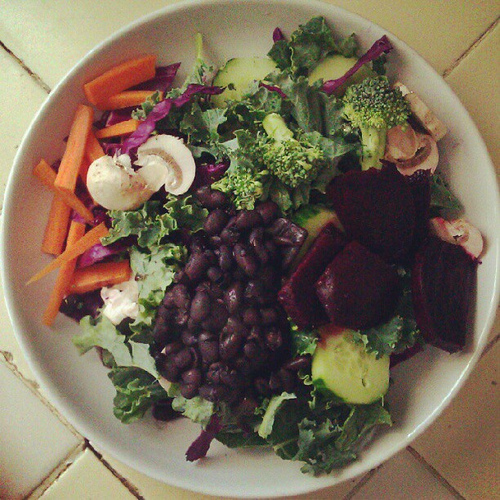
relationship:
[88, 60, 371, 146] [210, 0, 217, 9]
vegetables on plate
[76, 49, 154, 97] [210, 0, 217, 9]
carrots on plate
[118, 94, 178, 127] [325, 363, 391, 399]
beet on top of cucumber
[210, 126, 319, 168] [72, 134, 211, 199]
broccoli next to mushrooms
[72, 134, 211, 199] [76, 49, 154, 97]
mushrooms next to carrots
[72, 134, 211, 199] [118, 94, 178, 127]
mushrooms under beet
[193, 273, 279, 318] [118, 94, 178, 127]
beans next to beet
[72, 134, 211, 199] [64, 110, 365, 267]
mushrooms in salad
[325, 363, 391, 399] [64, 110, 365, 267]
cucumber in salad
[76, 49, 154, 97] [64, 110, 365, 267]
carrots in salad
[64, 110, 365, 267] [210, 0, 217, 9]
salad on plate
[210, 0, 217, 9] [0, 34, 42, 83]
plate on tile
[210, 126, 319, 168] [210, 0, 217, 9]
broccoli on plate